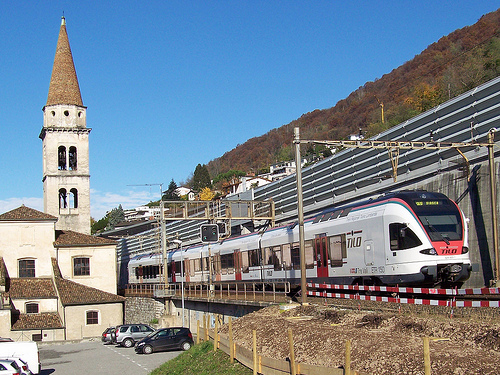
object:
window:
[220, 254, 237, 268]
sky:
[0, 1, 500, 222]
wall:
[66, 301, 124, 340]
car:
[135, 325, 192, 354]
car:
[112, 323, 154, 347]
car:
[100, 327, 115, 344]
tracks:
[125, 277, 497, 309]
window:
[19, 270, 37, 278]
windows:
[148, 233, 362, 277]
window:
[415, 210, 462, 241]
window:
[79, 265, 92, 275]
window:
[387, 222, 423, 253]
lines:
[388, 90, 500, 142]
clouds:
[0, 185, 158, 220]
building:
[0, 203, 126, 341]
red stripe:
[352, 196, 396, 211]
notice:
[305, 280, 500, 308]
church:
[0, 11, 124, 345]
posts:
[211, 315, 221, 354]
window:
[201, 257, 211, 272]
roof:
[0, 203, 56, 225]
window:
[25, 302, 41, 316]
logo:
[344, 228, 365, 250]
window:
[315, 234, 321, 266]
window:
[88, 317, 93, 324]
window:
[321, 238, 328, 265]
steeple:
[41, 8, 87, 108]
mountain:
[162, 7, 499, 201]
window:
[280, 241, 293, 269]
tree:
[439, 47, 471, 99]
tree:
[158, 175, 185, 203]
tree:
[192, 162, 216, 193]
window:
[73, 257, 89, 277]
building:
[40, 10, 92, 238]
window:
[305, 240, 315, 269]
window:
[291, 243, 298, 268]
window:
[281, 243, 291, 265]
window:
[271, 247, 284, 271]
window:
[263, 247, 272, 265]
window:
[249, 248, 259, 265]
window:
[174, 259, 182, 275]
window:
[225, 254, 234, 273]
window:
[201, 257, 208, 273]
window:
[190, 258, 192, 273]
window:
[168, 264, 175, 277]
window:
[173, 262, 180, 277]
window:
[153, 265, 156, 276]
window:
[149, 265, 152, 275]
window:
[146, 267, 152, 277]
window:
[141, 264, 146, 277]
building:
[93, 79, 500, 303]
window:
[290, 242, 302, 268]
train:
[117, 188, 474, 288]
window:
[327, 234, 344, 264]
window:
[259, 237, 286, 272]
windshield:
[408, 207, 462, 240]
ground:
[34, 337, 180, 374]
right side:
[128, 199, 387, 280]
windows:
[143, 254, 353, 274]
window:
[26, 259, 36, 270]